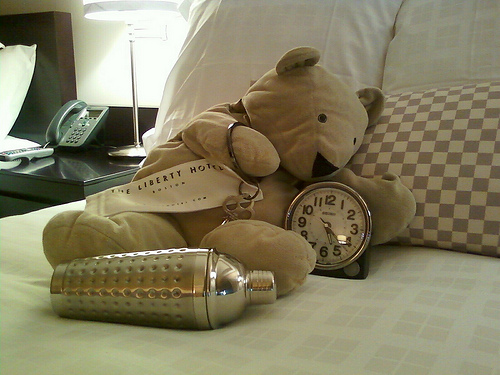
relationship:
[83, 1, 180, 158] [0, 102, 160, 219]
lamp on night stand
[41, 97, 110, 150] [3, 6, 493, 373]
telephone on bed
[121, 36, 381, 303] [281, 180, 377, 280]
bear with a clock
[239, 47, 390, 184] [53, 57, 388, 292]
head of a teddy bear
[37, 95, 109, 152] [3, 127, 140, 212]
phone on night stand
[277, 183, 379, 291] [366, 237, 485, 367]
clock in bed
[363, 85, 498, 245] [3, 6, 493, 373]
pillow on bed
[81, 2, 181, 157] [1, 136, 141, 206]
white lamp on end table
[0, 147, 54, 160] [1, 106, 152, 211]
remote sitting on end table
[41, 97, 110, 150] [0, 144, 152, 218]
telephone on table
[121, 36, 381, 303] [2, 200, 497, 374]
bear in bed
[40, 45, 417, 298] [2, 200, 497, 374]
small doll in bed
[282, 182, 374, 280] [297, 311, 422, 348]
clock sitting on bed